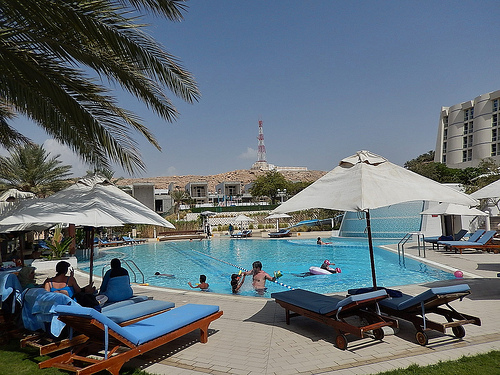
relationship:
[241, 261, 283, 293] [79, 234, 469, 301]
person in pool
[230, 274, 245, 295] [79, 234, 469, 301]
person in pool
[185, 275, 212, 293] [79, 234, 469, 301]
person in pool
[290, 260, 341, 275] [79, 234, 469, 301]
person in pool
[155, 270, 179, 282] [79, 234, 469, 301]
person in pool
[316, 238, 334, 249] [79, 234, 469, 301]
person in pool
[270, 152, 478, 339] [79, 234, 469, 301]
umbrella at pool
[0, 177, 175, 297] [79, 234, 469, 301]
umbrella at pool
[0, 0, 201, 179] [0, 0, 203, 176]
leaves of tree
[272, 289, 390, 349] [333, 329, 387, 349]
lounge chair with wheels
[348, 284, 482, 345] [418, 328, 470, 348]
lounge chair with wheels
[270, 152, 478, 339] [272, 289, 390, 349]
umbrella above lounge chair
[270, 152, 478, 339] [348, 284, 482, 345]
umbrella above lounge chair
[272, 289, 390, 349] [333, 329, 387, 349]
lounge chair has wheels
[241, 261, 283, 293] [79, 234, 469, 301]
man playing in pool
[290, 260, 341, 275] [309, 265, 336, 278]
person with float toy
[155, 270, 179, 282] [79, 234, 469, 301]
person playing in pool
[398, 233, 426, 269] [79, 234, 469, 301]
railing of pool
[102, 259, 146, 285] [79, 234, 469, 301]
railing of pool